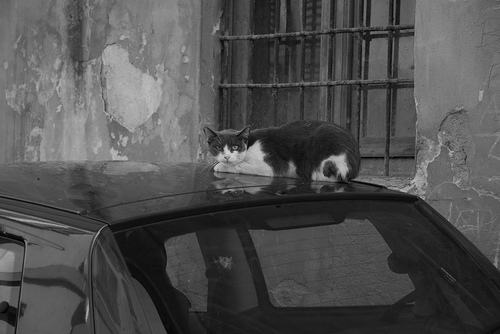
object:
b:
[478, 12, 498, 55]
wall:
[3, 1, 496, 307]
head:
[202, 125, 251, 166]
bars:
[213, 21, 418, 42]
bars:
[222, 74, 417, 90]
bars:
[382, 2, 397, 177]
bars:
[345, 4, 360, 131]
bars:
[267, 0, 282, 122]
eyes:
[231, 145, 239, 152]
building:
[0, 0, 498, 334]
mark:
[98, 42, 163, 129]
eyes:
[214, 144, 224, 151]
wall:
[428, 12, 495, 153]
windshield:
[90, 200, 499, 334]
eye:
[231, 143, 240, 150]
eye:
[215, 143, 223, 151]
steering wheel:
[386, 287, 448, 329]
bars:
[265, 0, 284, 128]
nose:
[223, 154, 231, 160]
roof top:
[0, 160, 418, 229]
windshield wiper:
[388, 204, 494, 321]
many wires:
[198, 115, 361, 187]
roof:
[0, 160, 420, 226]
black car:
[1, 156, 498, 332]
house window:
[215, 11, 418, 177]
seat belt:
[200, 239, 240, 316]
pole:
[384, 3, 398, 180]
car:
[0, 157, 500, 334]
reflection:
[2, 211, 139, 324]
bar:
[238, 4, 254, 127]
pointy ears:
[202, 125, 218, 138]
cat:
[204, 117, 365, 186]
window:
[221, 0, 418, 177]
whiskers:
[236, 157, 252, 166]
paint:
[28, 172, 118, 231]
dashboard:
[306, 301, 468, 331]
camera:
[0, 54, 481, 316]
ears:
[202, 125, 218, 139]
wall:
[64, 13, 201, 148]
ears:
[237, 124, 252, 137]